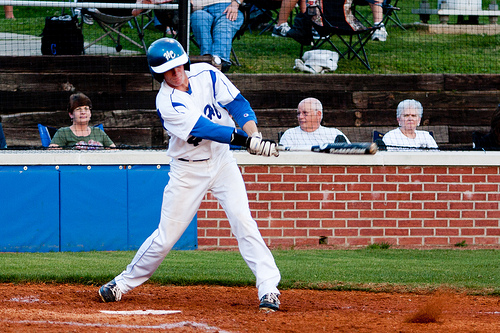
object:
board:
[57, 166, 129, 253]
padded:
[1, 165, 199, 254]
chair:
[38, 124, 52, 147]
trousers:
[116, 157, 281, 299]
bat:
[277, 142, 379, 156]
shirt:
[279, 126, 352, 154]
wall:
[0, 56, 500, 149]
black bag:
[39, 17, 85, 56]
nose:
[172, 71, 180, 76]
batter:
[97, 37, 286, 313]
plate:
[98, 310, 183, 316]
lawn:
[0, 251, 500, 290]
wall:
[197, 164, 497, 251]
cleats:
[97, 277, 121, 302]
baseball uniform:
[117, 60, 280, 300]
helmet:
[146, 37, 190, 84]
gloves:
[249, 139, 281, 158]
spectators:
[382, 98, 439, 150]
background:
[2, 0, 499, 150]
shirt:
[51, 126, 115, 149]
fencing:
[0, 0, 497, 74]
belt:
[173, 157, 211, 163]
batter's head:
[162, 54, 185, 87]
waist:
[166, 147, 232, 162]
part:
[398, 219, 421, 228]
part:
[401, 264, 421, 273]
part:
[163, 51, 177, 60]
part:
[164, 224, 174, 240]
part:
[97, 214, 109, 228]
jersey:
[155, 63, 241, 159]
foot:
[98, 277, 122, 302]